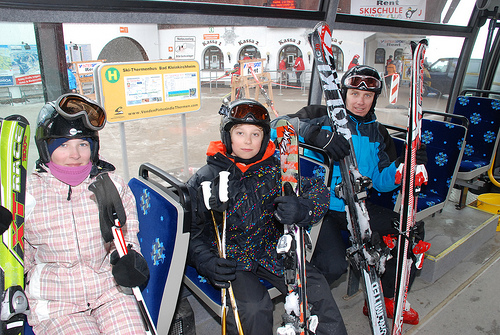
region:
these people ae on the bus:
[13, 27, 461, 311]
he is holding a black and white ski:
[303, 23, 389, 290]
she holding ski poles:
[192, 162, 254, 317]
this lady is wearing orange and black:
[198, 98, 278, 175]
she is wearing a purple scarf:
[52, 155, 99, 192]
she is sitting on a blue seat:
[119, 156, 221, 317]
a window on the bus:
[54, 28, 451, 138]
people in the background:
[274, 40, 311, 89]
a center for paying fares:
[153, 18, 428, 89]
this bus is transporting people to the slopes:
[31, 52, 484, 278]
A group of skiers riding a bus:
[17, 43, 459, 332]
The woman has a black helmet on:
[219, 96, 276, 156]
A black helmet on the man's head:
[337, 65, 392, 108]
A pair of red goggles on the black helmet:
[228, 103, 270, 120]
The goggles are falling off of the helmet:
[53, 88, 112, 133]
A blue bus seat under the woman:
[115, 178, 197, 330]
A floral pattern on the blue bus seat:
[454, 96, 492, 160]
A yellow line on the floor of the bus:
[427, 225, 489, 267]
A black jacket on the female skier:
[205, 171, 294, 278]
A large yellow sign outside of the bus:
[91, 55, 211, 119]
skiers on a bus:
[28, 31, 465, 303]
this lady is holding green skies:
[14, 58, 148, 330]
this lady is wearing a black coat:
[187, 86, 317, 308]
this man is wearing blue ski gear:
[292, 66, 409, 263]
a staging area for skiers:
[46, 24, 428, 122]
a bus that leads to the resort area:
[12, 54, 481, 316]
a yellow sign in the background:
[91, 53, 212, 125]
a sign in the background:
[231, 56, 282, 107]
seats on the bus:
[424, 71, 494, 226]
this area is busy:
[9, 32, 496, 136]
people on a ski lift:
[0, 36, 464, 333]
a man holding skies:
[286, 31, 419, 329]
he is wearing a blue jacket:
[283, 88, 395, 208]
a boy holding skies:
[177, 99, 344, 331]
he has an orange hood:
[200, 137, 274, 179]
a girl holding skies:
[4, 89, 161, 330]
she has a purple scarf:
[42, 160, 97, 187]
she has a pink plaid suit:
[12, 161, 162, 331]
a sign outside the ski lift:
[87, 55, 206, 123]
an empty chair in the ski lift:
[434, 76, 498, 198]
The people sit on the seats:
[1, 19, 433, 334]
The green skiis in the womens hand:
[1, 112, 34, 323]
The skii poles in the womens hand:
[201, 169, 248, 334]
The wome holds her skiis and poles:
[2, 79, 152, 334]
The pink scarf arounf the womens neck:
[46, 158, 101, 193]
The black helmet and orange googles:
[336, 61, 386, 120]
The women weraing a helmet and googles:
[209, 90, 276, 165]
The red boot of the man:
[358, 286, 428, 326]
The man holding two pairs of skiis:
[316, 18, 451, 333]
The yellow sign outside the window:
[92, 60, 204, 120]